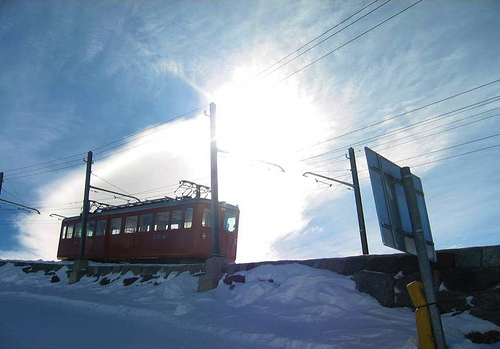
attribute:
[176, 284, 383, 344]
snow — Pile 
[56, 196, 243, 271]
tram car — red 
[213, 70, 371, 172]
sunlight — shining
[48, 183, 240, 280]
train — Red 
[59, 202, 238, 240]
windows — glass 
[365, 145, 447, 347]
sign — white 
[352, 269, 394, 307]
rock — Large 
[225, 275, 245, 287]
rock — Large 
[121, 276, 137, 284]
rock — Large 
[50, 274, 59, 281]
rock — Large 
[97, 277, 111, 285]
rock — Large 